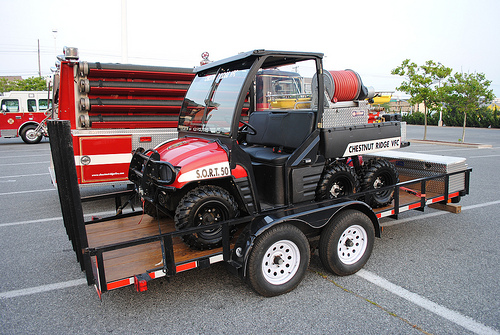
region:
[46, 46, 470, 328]
Truck on the road.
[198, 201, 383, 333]
Wheels on the road.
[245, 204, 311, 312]
Hub caps on the tire.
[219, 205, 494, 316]
Black tires on the vehicle.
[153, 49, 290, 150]
Windshield on the vehicle.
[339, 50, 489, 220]
Trees on the sidewalk.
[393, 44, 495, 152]
Green trees.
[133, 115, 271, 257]
Black wheels on the vehicle on the cart.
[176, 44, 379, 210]
Door on the vehicle.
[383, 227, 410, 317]
White line on the road.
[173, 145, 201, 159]
the atv is red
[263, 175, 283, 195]
the atv is black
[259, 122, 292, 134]
the seats are not ripped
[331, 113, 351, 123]
the toolbox is silver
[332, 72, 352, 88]
the cable is red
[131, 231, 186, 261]
therail is black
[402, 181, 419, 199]
the tie down is red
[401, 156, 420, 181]
the toolbox is diamond plated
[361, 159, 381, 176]
the tire have a lot of tread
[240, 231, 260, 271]
the fender is crushed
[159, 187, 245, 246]
small black wheel of car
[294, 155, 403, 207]
two small back wheels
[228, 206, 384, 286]
two black wheels on trailer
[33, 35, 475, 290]
trailer holding small car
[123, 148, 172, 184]
black bumper on front of car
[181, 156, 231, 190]
white on side of car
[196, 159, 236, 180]
black writing on side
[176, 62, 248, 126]
front wind shield of car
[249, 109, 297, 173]
black seats inside car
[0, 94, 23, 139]
side door to fire truck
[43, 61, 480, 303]
an ATV parked on a trailer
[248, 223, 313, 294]
the wheel of a trailer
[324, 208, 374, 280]
the wheel of a trailer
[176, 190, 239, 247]
the wheel of an ATV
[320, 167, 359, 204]
the wheel of an ATV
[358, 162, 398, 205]
the wheel of an ATV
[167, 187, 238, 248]
the front wheel of an ATV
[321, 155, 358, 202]
the rear wheel of an ATV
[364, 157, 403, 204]
the rear wheel of an ATV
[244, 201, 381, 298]
the wheels of a trailer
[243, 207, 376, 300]
Two black round tires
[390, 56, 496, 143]
Green leaves on two trees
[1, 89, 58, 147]
A red and white bus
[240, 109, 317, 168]
A black leather seat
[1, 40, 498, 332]
Two vehicles at a parking lot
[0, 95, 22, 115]
Window on a bus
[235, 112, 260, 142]
A black steering wheel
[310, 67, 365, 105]
A roll of red rope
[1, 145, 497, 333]
White lines on the parking lot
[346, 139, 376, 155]
The word "CHESTNUT" on side of a vehicle